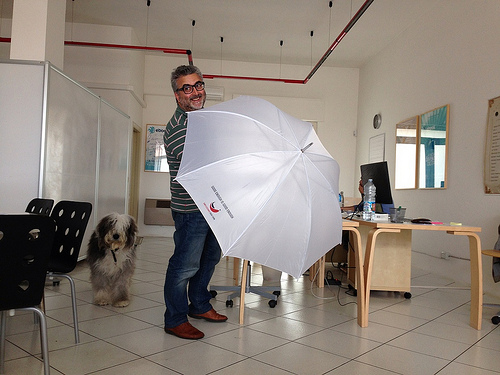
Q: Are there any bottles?
A: Yes, there is a bottle.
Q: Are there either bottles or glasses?
A: Yes, there is a bottle.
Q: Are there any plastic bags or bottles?
A: Yes, there is a plastic bottle.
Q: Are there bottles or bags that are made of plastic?
A: Yes, the bottle is made of plastic.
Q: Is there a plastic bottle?
A: Yes, there is a bottle that is made of plastic.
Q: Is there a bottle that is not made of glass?
A: Yes, there is a bottle that is made of plastic.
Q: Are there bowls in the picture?
A: No, there are no bowls.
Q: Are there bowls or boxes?
A: No, there are no bowls or boxes.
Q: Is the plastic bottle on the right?
A: Yes, the bottle is on the right of the image.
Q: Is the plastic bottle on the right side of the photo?
A: Yes, the bottle is on the right of the image.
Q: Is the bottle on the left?
A: No, the bottle is on the right of the image.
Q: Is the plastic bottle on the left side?
A: No, the bottle is on the right of the image.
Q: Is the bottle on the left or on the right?
A: The bottle is on the right of the image.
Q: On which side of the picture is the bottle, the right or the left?
A: The bottle is on the right of the image.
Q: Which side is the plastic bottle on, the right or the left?
A: The bottle is on the right of the image.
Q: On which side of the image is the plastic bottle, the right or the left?
A: The bottle is on the right of the image.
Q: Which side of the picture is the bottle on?
A: The bottle is on the right of the image.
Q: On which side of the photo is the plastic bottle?
A: The bottle is on the right of the image.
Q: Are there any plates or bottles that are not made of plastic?
A: No, there is a bottle but it is made of plastic.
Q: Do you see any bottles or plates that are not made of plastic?
A: No, there is a bottle but it is made of plastic.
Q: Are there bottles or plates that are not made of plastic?
A: No, there is a bottle but it is made of plastic.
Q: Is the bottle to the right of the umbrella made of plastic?
A: Yes, the bottle is made of plastic.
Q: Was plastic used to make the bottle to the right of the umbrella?
A: Yes, the bottle is made of plastic.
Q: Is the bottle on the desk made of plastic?
A: Yes, the bottle is made of plastic.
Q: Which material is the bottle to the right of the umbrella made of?
A: The bottle is made of plastic.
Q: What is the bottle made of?
A: The bottle is made of plastic.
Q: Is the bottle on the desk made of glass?
A: No, the bottle is made of plastic.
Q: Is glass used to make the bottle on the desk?
A: No, the bottle is made of plastic.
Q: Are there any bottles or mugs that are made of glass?
A: No, there is a bottle but it is made of plastic.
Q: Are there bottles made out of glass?
A: No, there is a bottle but it is made of plastic.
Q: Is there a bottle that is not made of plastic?
A: No, there is a bottle but it is made of plastic.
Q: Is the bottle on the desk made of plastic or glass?
A: The bottle is made of plastic.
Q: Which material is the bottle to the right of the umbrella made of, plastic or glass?
A: The bottle is made of plastic.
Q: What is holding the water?
A: The bottle is holding the water.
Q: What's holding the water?
A: The bottle is holding the water.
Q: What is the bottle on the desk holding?
A: The bottle is holding the water.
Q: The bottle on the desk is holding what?
A: The bottle is holding the water.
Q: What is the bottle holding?
A: The bottle is holding the water.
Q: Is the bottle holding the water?
A: Yes, the bottle is holding the water.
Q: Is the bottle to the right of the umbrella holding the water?
A: Yes, the bottle is holding the water.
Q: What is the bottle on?
A: The bottle is on the desk.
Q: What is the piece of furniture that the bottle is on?
A: The piece of furniture is a desk.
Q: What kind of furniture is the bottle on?
A: The bottle is on the desk.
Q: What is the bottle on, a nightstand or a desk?
A: The bottle is on a desk.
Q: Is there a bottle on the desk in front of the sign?
A: Yes, there is a bottle on the desk.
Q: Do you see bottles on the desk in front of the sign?
A: Yes, there is a bottle on the desk.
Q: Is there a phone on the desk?
A: No, there is a bottle on the desk.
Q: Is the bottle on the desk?
A: Yes, the bottle is on the desk.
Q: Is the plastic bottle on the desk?
A: Yes, the bottle is on the desk.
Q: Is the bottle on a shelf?
A: No, the bottle is on the desk.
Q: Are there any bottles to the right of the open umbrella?
A: Yes, there is a bottle to the right of the umbrella.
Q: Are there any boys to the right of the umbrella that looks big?
A: No, there is a bottle to the right of the umbrella.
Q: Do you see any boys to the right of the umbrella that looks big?
A: No, there is a bottle to the right of the umbrella.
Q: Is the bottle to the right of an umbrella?
A: Yes, the bottle is to the right of an umbrella.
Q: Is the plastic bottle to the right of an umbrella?
A: Yes, the bottle is to the right of an umbrella.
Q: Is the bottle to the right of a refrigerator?
A: No, the bottle is to the right of an umbrella.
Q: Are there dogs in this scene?
A: Yes, there is a dog.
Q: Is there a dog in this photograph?
A: Yes, there is a dog.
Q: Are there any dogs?
A: Yes, there is a dog.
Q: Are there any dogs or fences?
A: Yes, there is a dog.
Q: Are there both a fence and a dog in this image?
A: No, there is a dog but no fences.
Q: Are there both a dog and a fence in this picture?
A: No, there is a dog but no fences.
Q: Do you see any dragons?
A: No, there are no dragons.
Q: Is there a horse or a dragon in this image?
A: No, there are no dragons or horses.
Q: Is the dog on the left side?
A: Yes, the dog is on the left of the image.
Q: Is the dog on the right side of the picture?
A: No, the dog is on the left of the image.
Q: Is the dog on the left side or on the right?
A: The dog is on the left of the image.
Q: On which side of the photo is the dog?
A: The dog is on the left of the image.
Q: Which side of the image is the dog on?
A: The dog is on the left of the image.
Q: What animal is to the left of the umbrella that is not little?
A: The animal is a dog.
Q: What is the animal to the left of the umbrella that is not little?
A: The animal is a dog.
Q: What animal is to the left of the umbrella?
A: The animal is a dog.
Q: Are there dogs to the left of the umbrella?
A: Yes, there is a dog to the left of the umbrella.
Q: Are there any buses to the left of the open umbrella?
A: No, there is a dog to the left of the umbrella.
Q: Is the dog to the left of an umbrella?
A: Yes, the dog is to the left of an umbrella.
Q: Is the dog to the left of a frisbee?
A: No, the dog is to the left of an umbrella.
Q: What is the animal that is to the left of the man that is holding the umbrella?
A: The animal is a dog.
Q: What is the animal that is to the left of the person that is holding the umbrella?
A: The animal is a dog.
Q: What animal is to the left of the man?
A: The animal is a dog.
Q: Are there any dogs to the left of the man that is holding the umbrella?
A: Yes, there is a dog to the left of the man.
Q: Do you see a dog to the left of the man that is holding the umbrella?
A: Yes, there is a dog to the left of the man.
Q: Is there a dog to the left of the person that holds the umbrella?
A: Yes, there is a dog to the left of the man.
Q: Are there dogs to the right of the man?
A: No, the dog is to the left of the man.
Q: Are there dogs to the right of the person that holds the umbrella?
A: No, the dog is to the left of the man.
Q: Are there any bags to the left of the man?
A: No, there is a dog to the left of the man.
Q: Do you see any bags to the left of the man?
A: No, there is a dog to the left of the man.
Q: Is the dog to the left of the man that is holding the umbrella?
A: Yes, the dog is to the left of the man.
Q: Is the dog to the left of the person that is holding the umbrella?
A: Yes, the dog is to the left of the man.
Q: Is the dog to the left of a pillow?
A: No, the dog is to the left of the man.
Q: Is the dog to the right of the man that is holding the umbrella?
A: No, the dog is to the left of the man.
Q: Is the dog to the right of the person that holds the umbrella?
A: No, the dog is to the left of the man.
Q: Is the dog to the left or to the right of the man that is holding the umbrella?
A: The dog is to the left of the man.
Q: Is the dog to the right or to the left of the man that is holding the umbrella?
A: The dog is to the left of the man.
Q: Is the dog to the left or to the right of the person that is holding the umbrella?
A: The dog is to the left of the man.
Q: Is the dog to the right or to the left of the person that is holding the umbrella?
A: The dog is to the left of the man.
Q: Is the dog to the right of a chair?
A: Yes, the dog is to the right of a chair.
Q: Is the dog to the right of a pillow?
A: No, the dog is to the right of a chair.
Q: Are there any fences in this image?
A: No, there are no fences.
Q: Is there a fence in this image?
A: No, there are no fences.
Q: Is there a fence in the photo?
A: No, there are no fences.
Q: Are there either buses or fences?
A: No, there are no fences or buses.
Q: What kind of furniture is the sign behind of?
A: The sign is behind the desk.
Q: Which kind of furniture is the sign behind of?
A: The sign is behind the desk.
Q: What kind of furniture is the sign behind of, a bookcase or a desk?
A: The sign is behind a desk.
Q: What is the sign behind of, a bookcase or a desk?
A: The sign is behind a desk.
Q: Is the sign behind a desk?
A: Yes, the sign is behind a desk.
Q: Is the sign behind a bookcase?
A: No, the sign is behind a desk.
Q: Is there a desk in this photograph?
A: Yes, there is a desk.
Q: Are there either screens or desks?
A: Yes, there is a desk.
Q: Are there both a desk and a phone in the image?
A: No, there is a desk but no phones.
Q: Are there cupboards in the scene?
A: No, there are no cupboards.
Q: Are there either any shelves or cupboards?
A: No, there are no cupboards or shelves.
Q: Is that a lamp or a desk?
A: That is a desk.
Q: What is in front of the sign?
A: The desk is in front of the sign.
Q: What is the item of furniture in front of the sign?
A: The piece of furniture is a desk.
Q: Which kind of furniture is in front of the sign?
A: The piece of furniture is a desk.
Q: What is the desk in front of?
A: The desk is in front of the sign.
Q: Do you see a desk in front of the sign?
A: Yes, there is a desk in front of the sign.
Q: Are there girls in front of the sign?
A: No, there is a desk in front of the sign.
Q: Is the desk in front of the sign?
A: Yes, the desk is in front of the sign.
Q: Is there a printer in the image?
A: No, there are no printers.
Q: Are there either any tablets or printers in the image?
A: No, there are no printers or tablets.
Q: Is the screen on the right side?
A: Yes, the screen is on the right of the image.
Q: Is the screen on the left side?
A: No, the screen is on the right of the image.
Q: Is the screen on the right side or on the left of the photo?
A: The screen is on the right of the image.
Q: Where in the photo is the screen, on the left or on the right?
A: The screen is on the right of the image.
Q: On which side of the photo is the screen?
A: The screen is on the right of the image.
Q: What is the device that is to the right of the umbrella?
A: The device is a screen.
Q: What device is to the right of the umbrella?
A: The device is a screen.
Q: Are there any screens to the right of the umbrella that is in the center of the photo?
A: Yes, there is a screen to the right of the umbrella.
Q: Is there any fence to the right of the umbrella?
A: No, there is a screen to the right of the umbrella.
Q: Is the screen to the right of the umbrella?
A: Yes, the screen is to the right of the umbrella.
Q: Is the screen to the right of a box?
A: No, the screen is to the right of the umbrella.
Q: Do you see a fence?
A: No, there are no fences.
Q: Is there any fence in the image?
A: No, there are no fences.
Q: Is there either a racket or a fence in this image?
A: No, there are no fences or rackets.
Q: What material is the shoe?
A: The shoe is made of leather.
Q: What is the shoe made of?
A: The shoe is made of leather.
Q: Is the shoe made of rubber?
A: No, the shoe is made of leather.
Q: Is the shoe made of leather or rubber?
A: The shoe is made of leather.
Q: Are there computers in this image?
A: Yes, there is a computer.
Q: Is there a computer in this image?
A: Yes, there is a computer.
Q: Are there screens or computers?
A: Yes, there is a computer.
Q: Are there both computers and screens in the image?
A: Yes, there are both a computer and a screen.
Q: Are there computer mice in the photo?
A: No, there are no computer mice.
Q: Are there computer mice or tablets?
A: No, there are no computer mice or tablets.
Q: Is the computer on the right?
A: Yes, the computer is on the right of the image.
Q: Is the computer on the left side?
A: No, the computer is on the right of the image.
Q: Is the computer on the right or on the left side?
A: The computer is on the right of the image.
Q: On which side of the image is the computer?
A: The computer is on the right of the image.